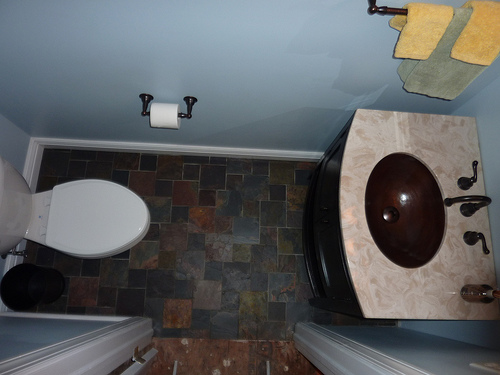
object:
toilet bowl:
[30, 175, 154, 262]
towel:
[387, 0, 456, 63]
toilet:
[2, 151, 171, 273]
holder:
[134, 91, 196, 120]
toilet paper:
[147, 102, 183, 131]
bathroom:
[3, 0, 500, 375]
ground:
[238, 114, 334, 165]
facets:
[445, 159, 494, 255]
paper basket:
[2, 262, 66, 308]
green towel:
[394, 8, 498, 102]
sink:
[361, 149, 450, 269]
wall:
[1, 0, 500, 257]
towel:
[448, 0, 500, 69]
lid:
[45, 177, 151, 262]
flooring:
[7, 141, 407, 375]